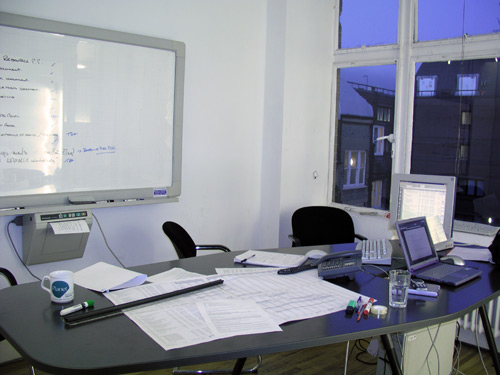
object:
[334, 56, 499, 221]
building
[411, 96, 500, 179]
wall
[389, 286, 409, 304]
water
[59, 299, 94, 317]
marker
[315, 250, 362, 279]
telephone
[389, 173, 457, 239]
monitor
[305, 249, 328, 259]
mouse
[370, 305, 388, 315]
tape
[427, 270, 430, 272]
key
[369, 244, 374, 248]
key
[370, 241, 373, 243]
key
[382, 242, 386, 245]
key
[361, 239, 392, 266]
keyboard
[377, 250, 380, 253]
key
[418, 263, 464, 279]
keyboard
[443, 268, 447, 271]
key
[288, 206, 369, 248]
chair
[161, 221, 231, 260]
chair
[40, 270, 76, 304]
cup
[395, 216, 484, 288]
laptop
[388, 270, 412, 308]
glass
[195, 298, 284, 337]
paper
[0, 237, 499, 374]
table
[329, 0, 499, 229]
windows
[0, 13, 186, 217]
board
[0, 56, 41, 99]
writing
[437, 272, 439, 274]
key